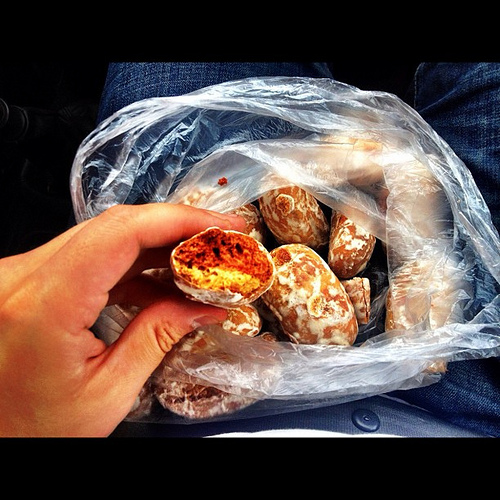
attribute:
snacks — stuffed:
[167, 229, 274, 303]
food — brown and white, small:
[148, 142, 423, 384]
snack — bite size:
[162, 225, 274, 315]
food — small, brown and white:
[275, 258, 332, 330]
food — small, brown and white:
[157, 159, 462, 417]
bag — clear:
[63, 74, 499, 418]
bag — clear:
[129, 126, 476, 413]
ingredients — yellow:
[179, 264, 252, 295]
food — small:
[177, 227, 378, 354]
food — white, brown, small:
[264, 237, 371, 349]